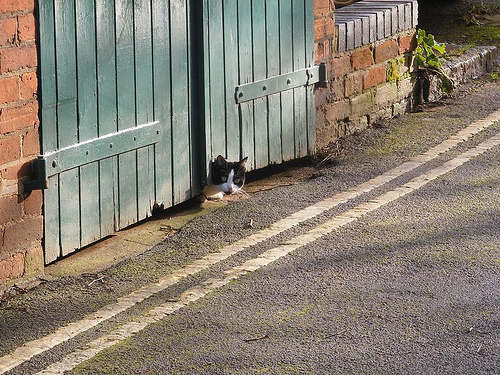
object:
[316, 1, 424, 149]
wall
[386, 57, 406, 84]
moss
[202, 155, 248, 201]
cat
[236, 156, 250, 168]
ear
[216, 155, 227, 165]
ear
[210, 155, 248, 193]
cat's head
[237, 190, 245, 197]
whiskers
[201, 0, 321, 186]
door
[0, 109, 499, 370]
line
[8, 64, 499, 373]
ground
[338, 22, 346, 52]
bricks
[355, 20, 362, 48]
bricks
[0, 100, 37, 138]
bricks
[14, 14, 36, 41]
bricks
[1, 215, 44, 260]
bricks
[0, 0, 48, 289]
wall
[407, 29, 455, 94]
plant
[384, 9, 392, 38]
bricks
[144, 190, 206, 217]
shadows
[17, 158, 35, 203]
shadows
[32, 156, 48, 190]
hinge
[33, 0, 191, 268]
door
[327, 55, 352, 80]
brick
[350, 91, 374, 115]
brick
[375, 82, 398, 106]
brick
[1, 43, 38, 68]
brick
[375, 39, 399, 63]
brick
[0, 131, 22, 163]
bricks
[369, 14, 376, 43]
bricks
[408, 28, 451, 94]
plant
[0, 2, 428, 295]
building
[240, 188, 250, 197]
whiskers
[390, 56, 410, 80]
brick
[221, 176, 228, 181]
eye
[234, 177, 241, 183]
eye